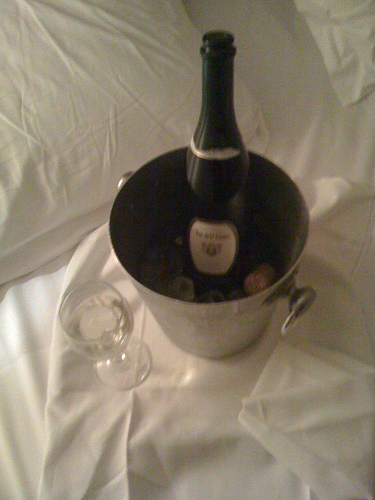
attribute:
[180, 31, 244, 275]
bottle — green, open, dark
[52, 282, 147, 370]
glass — clear, white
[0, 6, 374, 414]
sheet — white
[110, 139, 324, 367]
bucket — grey, silver, full